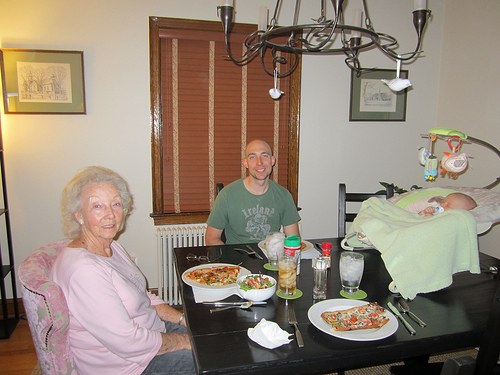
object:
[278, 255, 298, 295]
glass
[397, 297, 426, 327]
spoon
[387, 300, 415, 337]
butter knife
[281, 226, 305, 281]
bottle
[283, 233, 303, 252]
lid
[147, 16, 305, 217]
blinds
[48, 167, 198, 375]
pink woman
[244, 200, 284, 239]
design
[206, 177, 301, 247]
shirt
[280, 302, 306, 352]
utensil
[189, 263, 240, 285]
food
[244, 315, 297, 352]
napkin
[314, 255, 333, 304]
glass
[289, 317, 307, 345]
fork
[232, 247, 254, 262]
utensil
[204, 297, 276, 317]
utensil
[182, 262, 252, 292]
plate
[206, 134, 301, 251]
man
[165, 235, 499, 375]
black table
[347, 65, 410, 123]
framed drawing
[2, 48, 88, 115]
framed drawing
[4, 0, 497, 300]
wall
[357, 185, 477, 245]
baby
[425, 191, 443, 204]
paci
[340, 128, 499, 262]
chair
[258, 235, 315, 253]
plate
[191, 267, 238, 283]
pizza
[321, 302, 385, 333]
pizza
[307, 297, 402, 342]
plate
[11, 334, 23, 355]
wood floor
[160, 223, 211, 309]
radiator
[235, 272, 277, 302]
bowl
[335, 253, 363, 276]
ice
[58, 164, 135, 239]
hair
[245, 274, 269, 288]
salad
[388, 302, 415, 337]
utinsil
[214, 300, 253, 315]
utinsil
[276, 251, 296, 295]
beverage